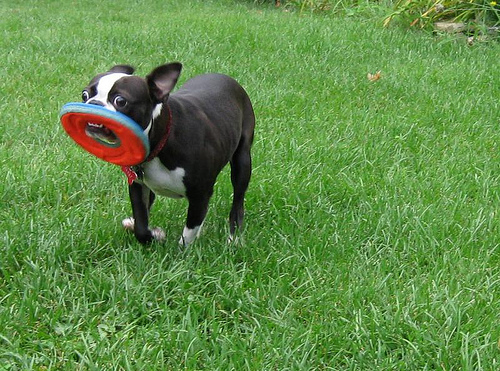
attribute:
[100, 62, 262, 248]
dog — black, running, alone, white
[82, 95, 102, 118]
nose — black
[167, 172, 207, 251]
leg — black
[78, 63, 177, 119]
head — black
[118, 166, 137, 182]
tag — red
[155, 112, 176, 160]
collar — red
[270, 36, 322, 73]
grass — green, white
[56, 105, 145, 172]
toy — red, blue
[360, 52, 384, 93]
leaf — brown, yellow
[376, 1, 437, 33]
leaves — green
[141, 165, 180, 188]
chest — white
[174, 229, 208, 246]
foot — white